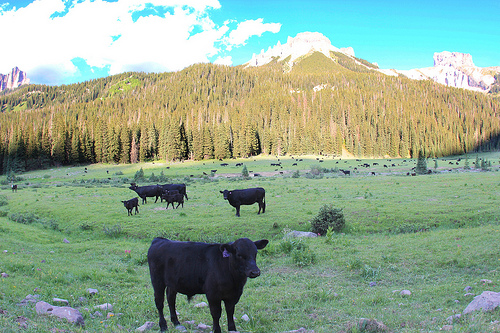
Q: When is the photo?
A: Daytime.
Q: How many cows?
A: Six.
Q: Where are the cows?
A: Field.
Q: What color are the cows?
A: Black.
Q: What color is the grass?
A: Green.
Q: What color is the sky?
A: Blue.